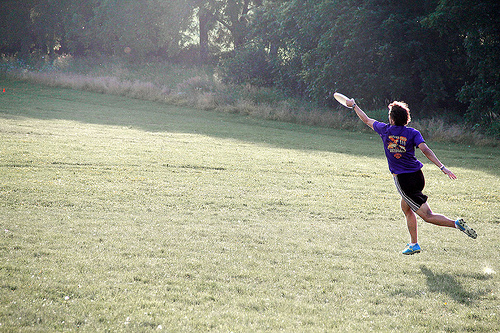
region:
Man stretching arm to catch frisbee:
[333, 92, 478, 257]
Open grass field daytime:
[0, 77, 497, 332]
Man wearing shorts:
[331, 92, 476, 254]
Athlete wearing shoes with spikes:
[331, 90, 478, 254]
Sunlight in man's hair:
[388, 102, 410, 126]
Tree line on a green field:
[4, 0, 499, 149]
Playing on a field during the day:
[0, 78, 496, 256]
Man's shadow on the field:
[420, 264, 482, 313]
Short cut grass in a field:
[9, 104, 184, 208]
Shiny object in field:
[481, 265, 495, 275]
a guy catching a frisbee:
[321, 72, 476, 264]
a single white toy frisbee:
[327, 85, 358, 107]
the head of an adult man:
[380, 91, 411, 128]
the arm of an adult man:
[341, 101, 373, 129]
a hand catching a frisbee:
[340, 95, 361, 110]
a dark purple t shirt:
[371, 116, 422, 168]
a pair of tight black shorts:
[388, 168, 438, 209]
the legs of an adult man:
[394, 206, 456, 244]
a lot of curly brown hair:
[388, 91, 412, 122]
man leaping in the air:
[328, 90, 479, 258]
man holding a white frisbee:
[331, 89, 478, 256]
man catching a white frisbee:
[327, 88, 479, 269]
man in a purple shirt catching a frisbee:
[331, 90, 478, 258]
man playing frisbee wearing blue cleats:
[331, 88, 480, 258]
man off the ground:
[325, 90, 480, 267]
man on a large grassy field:
[1, 1, 498, 331]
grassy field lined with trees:
[1, 0, 499, 332]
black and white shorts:
[391, 168, 429, 211]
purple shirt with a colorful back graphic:
[371, 118, 428, 175]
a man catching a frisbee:
[298, 43, 465, 275]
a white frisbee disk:
[321, 78, 357, 113]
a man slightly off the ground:
[316, 64, 487, 267]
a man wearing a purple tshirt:
[365, 106, 435, 176]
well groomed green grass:
[52, 163, 169, 283]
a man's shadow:
[394, 264, 484, 323]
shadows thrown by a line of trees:
[27, 89, 217, 158]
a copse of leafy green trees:
[221, 15, 361, 69]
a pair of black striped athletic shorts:
[384, 166, 444, 209]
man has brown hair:
[377, 96, 402, 128]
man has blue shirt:
[372, 115, 427, 177]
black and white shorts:
[389, 159, 419, 216]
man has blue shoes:
[391, 218, 428, 265]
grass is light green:
[155, 213, 332, 286]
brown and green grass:
[73, 62, 284, 118]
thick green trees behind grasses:
[1, 10, 465, 107]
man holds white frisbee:
[312, 84, 369, 124]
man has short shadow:
[387, 258, 488, 317]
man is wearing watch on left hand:
[344, 95, 359, 118]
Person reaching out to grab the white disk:
[312, 70, 489, 282]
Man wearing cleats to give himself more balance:
[321, 74, 476, 292]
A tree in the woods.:
[181, 2, 233, 84]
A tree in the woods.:
[234, 0, 318, 96]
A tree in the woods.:
[306, 4, 370, 106]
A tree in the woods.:
[366, 6, 491, 126]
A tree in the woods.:
[425, 9, 490, 134]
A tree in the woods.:
[109, 0, 164, 73]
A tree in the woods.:
[46, 4, 92, 62]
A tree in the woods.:
[6, 0, 46, 65]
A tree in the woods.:
[114, 5, 296, 82]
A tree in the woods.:
[416, 5, 482, 117]